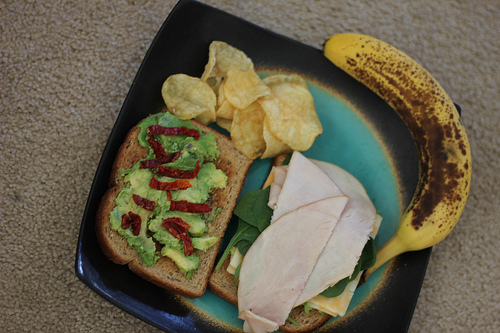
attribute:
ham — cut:
[228, 149, 379, 331]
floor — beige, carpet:
[5, 4, 482, 320]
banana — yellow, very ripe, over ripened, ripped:
[316, 27, 474, 292]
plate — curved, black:
[88, 14, 482, 331]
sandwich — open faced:
[75, 91, 289, 311]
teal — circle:
[268, 115, 408, 190]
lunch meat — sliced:
[251, 154, 345, 327]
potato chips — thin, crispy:
[160, 38, 325, 155]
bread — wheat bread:
[125, 160, 223, 266]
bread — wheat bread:
[142, 139, 290, 277]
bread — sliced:
[99, 111, 253, 297]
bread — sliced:
[209, 256, 331, 332]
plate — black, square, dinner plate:
[73, 0, 459, 330]